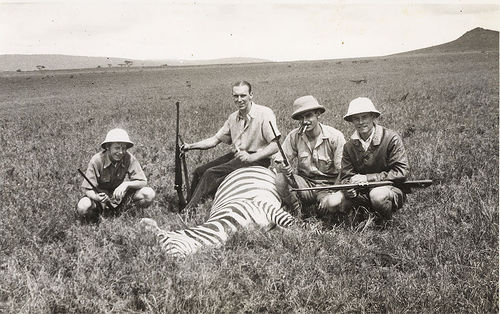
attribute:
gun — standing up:
[168, 97, 188, 195]